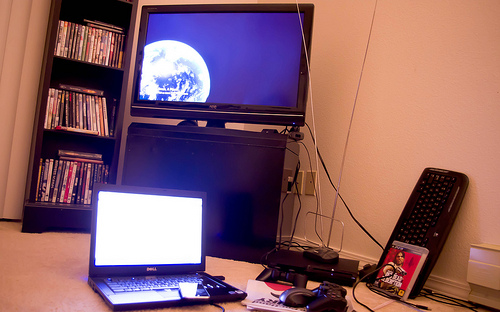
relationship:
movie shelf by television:
[23, 4, 139, 230] [130, 2, 321, 127]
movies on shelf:
[55, 19, 124, 67] [52, 51, 124, 73]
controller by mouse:
[309, 279, 348, 311] [275, 284, 312, 307]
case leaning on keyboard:
[361, 157, 498, 285] [367, 158, 471, 303]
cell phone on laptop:
[175, 280, 210, 303] [87, 181, 247, 310]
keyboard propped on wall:
[88, 257, 263, 308] [293, 23, 497, 263]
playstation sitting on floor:
[257, 246, 358, 288] [230, 264, 255, 275]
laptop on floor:
[87, 181, 247, 310] [9, 217, 471, 308]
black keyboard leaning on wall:
[372, 165, 471, 293] [317, 17, 493, 160]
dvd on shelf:
[29, 17, 125, 206] [26, 0, 141, 245]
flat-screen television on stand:
[140, 2, 315, 124] [117, 122, 299, 263]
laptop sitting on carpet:
[87, 181, 247, 310] [10, 219, 406, 309]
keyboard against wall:
[362, 155, 474, 310] [6, 6, 493, 300]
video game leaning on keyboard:
[371, 239, 427, 301] [366, 167, 469, 298]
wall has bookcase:
[6, 6, 493, 300] [27, 3, 132, 229]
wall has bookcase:
[340, 156, 405, 200] [27, 3, 132, 229]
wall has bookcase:
[2, 0, 25, 211] [27, 3, 132, 229]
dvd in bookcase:
[29, 17, 125, 206] [27, 3, 132, 229]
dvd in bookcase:
[56, 151, 101, 156] [27, 3, 132, 229]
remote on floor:
[247, 283, 301, 310] [0, 219, 498, 309]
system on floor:
[266, 242, 363, 287] [0, 232, 464, 309]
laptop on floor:
[87, 181, 247, 310] [12, 223, 64, 283]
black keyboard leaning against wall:
[372, 165, 471, 293] [293, 23, 497, 263]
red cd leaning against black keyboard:
[371, 239, 431, 296] [372, 165, 471, 293]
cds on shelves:
[35, 16, 123, 204] [17, 15, 125, 263]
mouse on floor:
[278, 286, 313, 307] [0, 219, 498, 309]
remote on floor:
[306, 280, 346, 305] [0, 219, 498, 309]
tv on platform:
[127, 2, 314, 127] [121, 121, 297, 263]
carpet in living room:
[1, 221, 484, 311] [2, 1, 495, 306]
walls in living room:
[321, 1, 498, 283] [2, 1, 495, 306]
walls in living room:
[1, 2, 41, 227] [2, 1, 495, 306]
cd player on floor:
[264, 246, 359, 286] [0, 219, 498, 309]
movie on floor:
[371, 237, 431, 302] [0, 219, 498, 309]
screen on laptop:
[93, 190, 201, 265] [87, 181, 247, 310]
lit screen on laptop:
[95, 189, 201, 264] [87, 181, 247, 310]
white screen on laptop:
[96, 187, 200, 264] [87, 181, 247, 310]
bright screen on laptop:
[93, 190, 201, 264] [87, 181, 247, 310]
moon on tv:
[142, 34, 213, 101] [119, 7, 366, 169]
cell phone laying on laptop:
[177, 281, 212, 299] [87, 181, 247, 310]